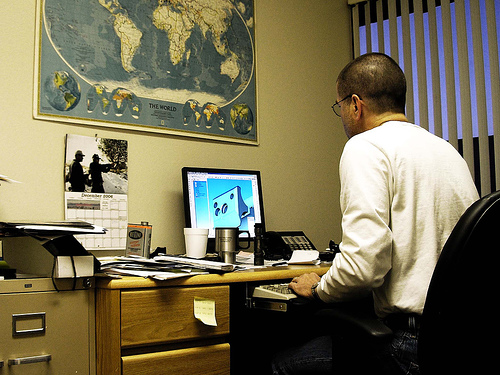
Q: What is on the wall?
A: A map.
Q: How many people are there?
A: One.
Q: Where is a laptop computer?
A: On the desk.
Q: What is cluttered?
A: The desk.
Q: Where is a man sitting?
A: In black chair.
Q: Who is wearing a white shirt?
A: A man.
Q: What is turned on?
A: A computer.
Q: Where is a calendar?
A: On the wall.